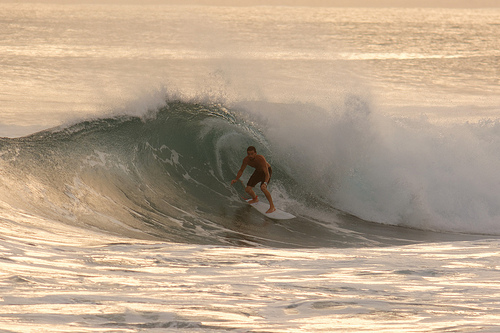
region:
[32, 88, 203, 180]
Large wave on the water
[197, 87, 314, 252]
Man surfboarding in middle of large wave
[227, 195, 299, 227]
White surfboard floating on the water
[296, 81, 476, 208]
Water splashing up from large wave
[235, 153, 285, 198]
Man wearing black swimming trunks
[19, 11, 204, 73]
Calm stretch of water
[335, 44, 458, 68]
Reflection from the sun on the water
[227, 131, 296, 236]
Man balancing on white surfboard on the water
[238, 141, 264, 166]
Man with short black hair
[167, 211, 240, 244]
Foam floating on the water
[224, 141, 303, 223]
man on surfboard in ocean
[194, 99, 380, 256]
man is riding waves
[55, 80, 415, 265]
tall waves in ocean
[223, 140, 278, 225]
man not wearing a shirt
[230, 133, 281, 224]
man in red shorts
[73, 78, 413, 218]
white waves of ocean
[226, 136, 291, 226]
surfing man with brown hair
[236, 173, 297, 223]
white surfboard of man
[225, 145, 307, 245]
man with wristband on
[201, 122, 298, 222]
man riding under wave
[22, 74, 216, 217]
Large wave in middle of water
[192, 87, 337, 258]
Man surfing in middle of large wave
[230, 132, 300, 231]
Man standing on white surfboard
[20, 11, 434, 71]
Large stretch of calm water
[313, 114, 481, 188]
Water splashing from large wave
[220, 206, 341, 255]
White surfboard floating on top of water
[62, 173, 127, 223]
Foam on the water created by a large wave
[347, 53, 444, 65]
Reflection of the sun on the water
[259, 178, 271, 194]
White bracelet on wrist of man surfboarding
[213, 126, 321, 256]
the man is surfing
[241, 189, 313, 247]
the surfboard is white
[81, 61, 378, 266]
the water has wave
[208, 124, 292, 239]
man is riding the waves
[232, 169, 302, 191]
the shorts are black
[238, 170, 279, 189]
man is wearing short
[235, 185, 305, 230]
surfboard on the water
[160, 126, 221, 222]
the water is gray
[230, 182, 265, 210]
the rope is red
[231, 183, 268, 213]
the rope is tied on the ankle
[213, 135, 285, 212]
man in water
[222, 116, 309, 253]
surfer on a board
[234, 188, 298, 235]
white surfboard under man's feet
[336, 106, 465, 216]
white waves in water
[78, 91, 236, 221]
wave in the water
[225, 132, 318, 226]
man in a wave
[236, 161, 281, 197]
shorts on a man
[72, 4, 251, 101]
calm water in background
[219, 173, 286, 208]
bent knees of man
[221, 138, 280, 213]
man with dark hair